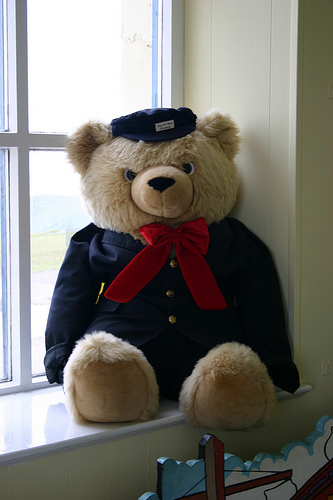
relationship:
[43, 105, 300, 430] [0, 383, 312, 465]
bear of window sill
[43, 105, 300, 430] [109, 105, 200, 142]
bear wearing cap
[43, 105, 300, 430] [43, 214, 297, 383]
bear wearing jacket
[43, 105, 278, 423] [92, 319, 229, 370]
bear wearing shorts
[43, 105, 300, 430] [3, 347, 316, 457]
bear sitting on ledge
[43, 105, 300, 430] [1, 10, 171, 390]
bear siting next to window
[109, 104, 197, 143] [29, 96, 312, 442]
cap on head of bear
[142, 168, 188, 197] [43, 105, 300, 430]
nose on bear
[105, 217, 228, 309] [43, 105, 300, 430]
bow on neck of bear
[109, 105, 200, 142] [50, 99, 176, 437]
cap on head of bear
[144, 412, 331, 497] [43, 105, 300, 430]
display beneath bear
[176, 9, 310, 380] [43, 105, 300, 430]
wall behind bear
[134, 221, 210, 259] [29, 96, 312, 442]
bow on neck of bear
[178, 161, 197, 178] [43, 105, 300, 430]
left eye on bear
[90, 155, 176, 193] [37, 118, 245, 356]
eye on bear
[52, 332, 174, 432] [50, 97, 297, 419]
foot on bear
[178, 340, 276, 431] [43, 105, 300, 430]
foot on bear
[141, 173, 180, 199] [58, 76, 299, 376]
nose on bear